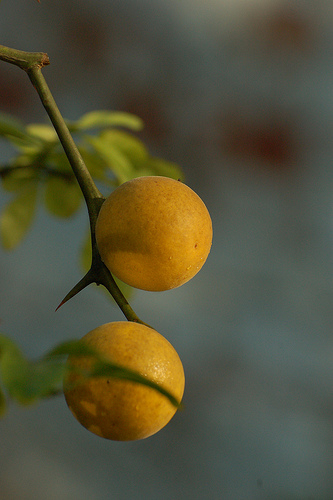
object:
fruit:
[95, 176, 214, 292]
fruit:
[62, 321, 186, 442]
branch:
[0, 45, 160, 333]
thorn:
[54, 272, 96, 312]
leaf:
[79, 133, 138, 185]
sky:
[1, 2, 333, 500]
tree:
[1, 44, 214, 444]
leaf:
[77, 108, 145, 133]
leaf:
[85, 362, 185, 412]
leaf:
[42, 173, 83, 225]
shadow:
[94, 231, 150, 259]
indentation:
[194, 243, 197, 248]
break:
[40, 52, 50, 67]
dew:
[187, 264, 192, 270]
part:
[63, 375, 186, 443]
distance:
[0, 1, 333, 499]